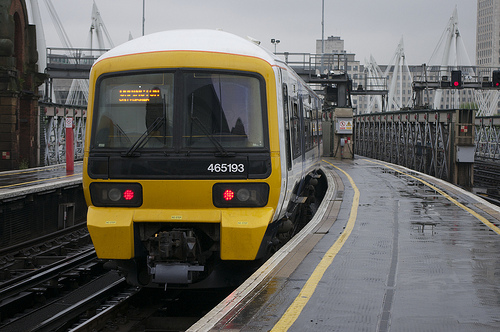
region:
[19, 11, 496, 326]
a rainy day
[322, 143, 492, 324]
the ground is wet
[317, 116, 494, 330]
no one is walking on the train platform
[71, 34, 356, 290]
a train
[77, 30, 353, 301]
a train is on the tracks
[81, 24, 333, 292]
the train is grey and yellow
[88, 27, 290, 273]
the front of the train is yellow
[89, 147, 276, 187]
the train is number 465193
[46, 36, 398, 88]
a metal bridge is over the train tracks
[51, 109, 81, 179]
an orange pole is beside the tracks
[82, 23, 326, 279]
front car of passenger train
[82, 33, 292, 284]
yellow passenger train car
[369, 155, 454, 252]
puddles on concrete platform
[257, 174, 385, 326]
yellow safety stripes on passenger platform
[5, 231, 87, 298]
metal railroad tracks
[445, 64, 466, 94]
railroad signal light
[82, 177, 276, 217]
passenger train front lights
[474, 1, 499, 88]
multistory office building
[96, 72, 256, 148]
reflection in front train window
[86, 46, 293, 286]
One train is running.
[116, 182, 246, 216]
Two red light is on in front of train.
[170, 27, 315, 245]
Train is yellow and white color.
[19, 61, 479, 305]
It is a rainy day.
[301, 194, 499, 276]
Yellow lines in the pavement.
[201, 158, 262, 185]
465193 is written in train.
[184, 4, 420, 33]
Sky is grey color.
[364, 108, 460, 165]
Rods are black color.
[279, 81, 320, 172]
Windows are attached to the sides of the train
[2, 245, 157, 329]
Tracks are brown color.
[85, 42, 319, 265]
Yellow and white train.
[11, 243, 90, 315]
Metal train tracks.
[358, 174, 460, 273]
Wet concrete sidewalk.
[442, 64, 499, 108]
Two traffic lights showing red light.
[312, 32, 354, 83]
Grey colored building in background.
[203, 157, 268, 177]
White colored number of train.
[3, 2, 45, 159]
Brick building left of train.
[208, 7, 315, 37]
Cloudy grey sky in background.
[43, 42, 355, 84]
Grey metal bridge in background.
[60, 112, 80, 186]
Red pole with white sign.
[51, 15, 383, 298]
a white and yellow train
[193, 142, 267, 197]
the train number is 465193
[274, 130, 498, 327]
the walkway is wet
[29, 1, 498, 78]
the sky is gray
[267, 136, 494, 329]
the walkway has yellow lines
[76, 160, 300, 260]
the bus has two red lights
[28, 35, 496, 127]
a bridge is behind the train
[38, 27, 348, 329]
the train is on train tracks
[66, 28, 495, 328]
the train is beside the walkway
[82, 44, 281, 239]
the train has a big windshield